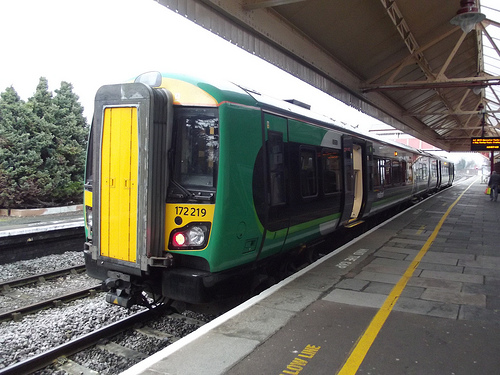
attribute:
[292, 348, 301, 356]
spot — white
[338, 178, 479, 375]
line — yellow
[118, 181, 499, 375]
platform — gray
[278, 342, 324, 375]
words — yellow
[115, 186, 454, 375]
edge — white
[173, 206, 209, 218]
words — black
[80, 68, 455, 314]
train — green, white, yellow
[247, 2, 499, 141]
beams — steel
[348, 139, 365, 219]
door — white, yellow, open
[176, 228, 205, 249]
light — on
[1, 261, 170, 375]
tracks — silver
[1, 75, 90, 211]
trees — green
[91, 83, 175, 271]
door — gray, yellow, closed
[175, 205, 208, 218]
numbers — black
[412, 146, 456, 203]
cars — green, white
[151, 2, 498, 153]
overhang — gray, brown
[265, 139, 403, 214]
windows — square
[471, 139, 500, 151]
sign — led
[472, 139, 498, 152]
writing — illuminated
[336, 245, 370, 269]
writing — white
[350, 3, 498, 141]
frame — metallic